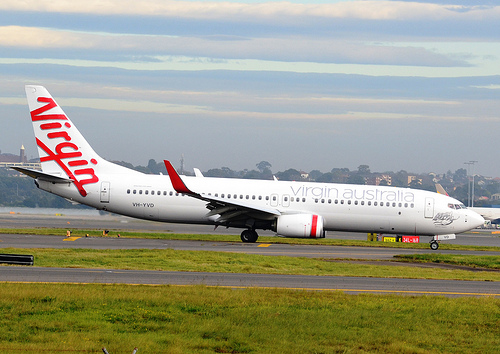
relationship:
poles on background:
[463, 157, 475, 208] [4, 159, 498, 198]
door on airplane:
[425, 197, 434, 217] [5, 83, 487, 245]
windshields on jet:
[435, 187, 497, 218] [22, 83, 466, 264]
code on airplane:
[134, 201, 154, 208] [11, 80, 489, 248]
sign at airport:
[401, 232, 423, 244] [2, 80, 488, 256]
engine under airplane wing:
[268, 211, 325, 238] [163, 159, 280, 218]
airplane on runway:
[5, 83, 487, 245] [0, 227, 497, 260]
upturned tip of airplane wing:
[160, 159, 188, 194] [144, 152, 290, 237]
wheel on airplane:
[430, 236, 440, 250] [11, 80, 489, 248]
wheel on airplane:
[241, 230, 259, 243] [11, 80, 489, 248]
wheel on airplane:
[245, 228, 258, 241] [11, 80, 489, 248]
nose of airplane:
[459, 206, 491, 236] [0, 57, 500, 293]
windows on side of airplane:
[134, 163, 420, 232] [37, 93, 498, 268]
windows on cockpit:
[448, 201, 466, 208] [8, 81, 485, 235]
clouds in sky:
[96, 21, 449, 138] [0, 3, 499, 182]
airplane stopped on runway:
[5, 83, 487, 245] [26, 229, 490, 304]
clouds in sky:
[0, 0, 500, 131] [263, 37, 358, 82]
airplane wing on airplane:
[163, 159, 280, 218] [11, 80, 489, 248]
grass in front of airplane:
[397, 245, 499, 270] [11, 80, 489, 248]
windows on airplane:
[126, 189, 420, 210] [11, 80, 489, 248]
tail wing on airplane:
[22, 81, 140, 176] [5, 83, 487, 245]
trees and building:
[3, 175, 26, 208] [7, 159, 42, 176]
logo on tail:
[26, 86, 97, 196] [25, 84, 142, 179]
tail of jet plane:
[25, 84, 142, 179] [8, 68, 489, 258]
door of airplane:
[423, 197, 433, 217] [11, 80, 489, 248]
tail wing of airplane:
[24, 85, 146, 178] [11, 80, 489, 248]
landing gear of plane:
[429, 234, 443, 252] [427, 241, 444, 253]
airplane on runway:
[5, 83, 487, 245] [0, 229, 500, 295]